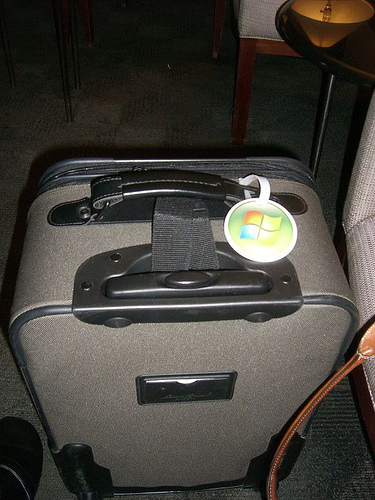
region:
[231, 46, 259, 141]
a leg of a chair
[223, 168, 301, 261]
a tag on luggage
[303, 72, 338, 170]
the leg of a table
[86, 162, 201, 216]
the handle of a luggage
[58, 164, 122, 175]
the zipper on luggage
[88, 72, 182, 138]
a gray carpet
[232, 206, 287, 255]
the Windows symbol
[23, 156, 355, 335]
a gray suitcase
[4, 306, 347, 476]
a gray suitcase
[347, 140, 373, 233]
the arm of a sofa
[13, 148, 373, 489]
A piece of luggage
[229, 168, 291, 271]
A microsoft tag on the luggage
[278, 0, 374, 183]
A table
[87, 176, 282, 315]
handles on the luggage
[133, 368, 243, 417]
an identification card slot on the luggage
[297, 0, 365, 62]
reflection of a lamp on the table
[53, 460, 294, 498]
wheels on the luggage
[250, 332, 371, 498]
A brown leather strap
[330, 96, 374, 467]
A white cloth seat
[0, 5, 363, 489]
some dark green carpet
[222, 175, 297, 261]
tag with windows symbol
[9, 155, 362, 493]
gray and black suitcase standing up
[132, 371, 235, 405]
black tag holder on suitcase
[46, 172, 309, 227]
handle on top of suitcase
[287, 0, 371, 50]
reflection of lamp cover on table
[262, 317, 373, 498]
brown leather strap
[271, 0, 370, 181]
black table made of reflective material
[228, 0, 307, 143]
white and brown chair for sitting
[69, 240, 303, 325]
portion where extended handle is tucked away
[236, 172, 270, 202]
blastic clip attached to suitcase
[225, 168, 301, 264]
A windows logo.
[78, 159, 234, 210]
The black bag handle.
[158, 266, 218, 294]
The button for the roller.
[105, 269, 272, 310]
The handle for the roller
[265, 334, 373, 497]
A brown bag starp.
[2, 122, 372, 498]
A grey suitcase.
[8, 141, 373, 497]
Luggage on the floor.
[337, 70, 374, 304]
The corner of the couch.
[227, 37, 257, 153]
The leg of a chair.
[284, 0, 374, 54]
The relflection of the lamp shade.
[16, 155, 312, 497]
Grey and black rolling luggage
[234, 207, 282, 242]
Microsoft Windows blue, red, white and yellow logo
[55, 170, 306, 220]
Suitcase carrying handle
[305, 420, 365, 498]
Grey carpeting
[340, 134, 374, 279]
Edge of light colored chair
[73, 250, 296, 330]
Pull handle retracted into luggage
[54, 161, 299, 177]
Zipper holding front of luggage closed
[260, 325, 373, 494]
Leather purse handle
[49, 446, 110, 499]
Wheel housing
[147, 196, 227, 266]
Shoulder strap